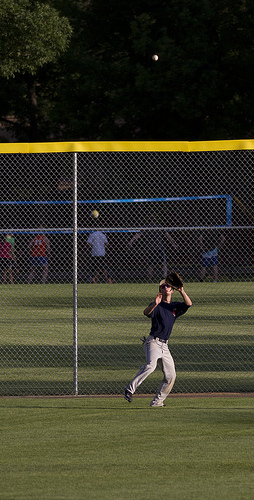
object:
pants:
[125, 334, 177, 408]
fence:
[0, 141, 254, 395]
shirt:
[32, 235, 46, 258]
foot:
[124, 380, 133, 403]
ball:
[151, 52, 159, 65]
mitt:
[164, 271, 184, 289]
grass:
[0, 398, 254, 485]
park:
[0, 53, 252, 405]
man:
[123, 267, 192, 407]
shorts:
[30, 256, 49, 276]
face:
[159, 281, 172, 295]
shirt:
[145, 295, 189, 343]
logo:
[172, 310, 177, 320]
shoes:
[123, 385, 165, 409]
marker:
[0, 138, 254, 154]